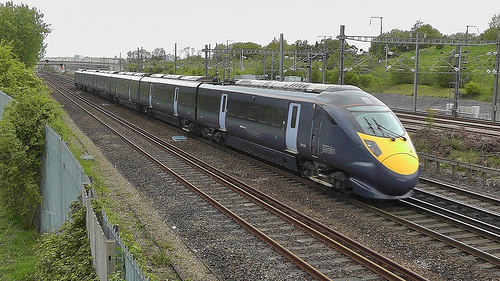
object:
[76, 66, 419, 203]
train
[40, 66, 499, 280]
tracks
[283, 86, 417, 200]
section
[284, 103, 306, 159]
door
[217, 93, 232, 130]
door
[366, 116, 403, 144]
wipers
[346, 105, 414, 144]
windshield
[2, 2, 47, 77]
tree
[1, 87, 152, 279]
fence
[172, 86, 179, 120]
door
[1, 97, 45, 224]
shrub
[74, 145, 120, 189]
grass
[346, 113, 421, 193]
train nose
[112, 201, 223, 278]
gravel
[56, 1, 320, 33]
sky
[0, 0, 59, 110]
trees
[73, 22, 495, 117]
power lines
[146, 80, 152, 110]
doors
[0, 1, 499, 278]
picture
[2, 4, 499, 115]
background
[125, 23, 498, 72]
trees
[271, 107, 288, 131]
window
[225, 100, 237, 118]
window